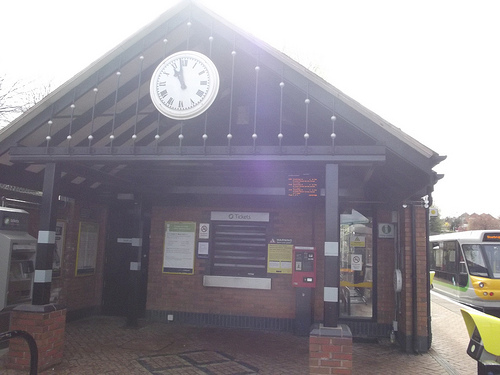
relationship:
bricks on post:
[302, 322, 359, 372] [319, 153, 354, 337]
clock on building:
[139, 47, 227, 119] [1, 0, 443, 359]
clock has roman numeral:
[149, 50, 221, 121] [194, 61, 200, 71]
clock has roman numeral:
[149, 50, 221, 121] [198, 76, 210, 88]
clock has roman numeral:
[149, 50, 221, 121] [176, 97, 185, 114]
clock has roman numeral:
[149, 50, 221, 121] [154, 86, 168, 100]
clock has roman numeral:
[149, 50, 221, 121] [159, 64, 169, 76]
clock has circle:
[149, 50, 221, 121] [175, 78, 189, 96]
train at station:
[427, 228, 499, 315] [6, 7, 498, 372]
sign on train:
[482, 230, 499, 244] [430, 230, 499, 307]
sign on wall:
[156, 217, 197, 277] [145, 200, 318, 337]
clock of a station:
[149, 50, 221, 121] [6, 7, 498, 372]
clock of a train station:
[149, 50, 221, 121] [4, 0, 455, 374]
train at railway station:
[424, 220, 499, 317] [0, 0, 472, 375]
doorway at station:
[89, 207, 143, 324] [6, 7, 498, 372]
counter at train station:
[139, 203, 336, 333] [4, 0, 455, 374]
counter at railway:
[143, 201, 337, 329] [5, 5, 498, 364]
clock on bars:
[149, 50, 221, 121] [45, 19, 345, 156]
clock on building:
[149, 50, 221, 121] [58, 59, 403, 174]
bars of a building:
[45, 19, 345, 156] [58, 59, 403, 174]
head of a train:
[458, 231, 498, 292] [425, 226, 498, 314]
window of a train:
[13, 191, 55, 251] [403, 194, 493, 336]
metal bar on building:
[106, 66, 123, 155] [1, 0, 443, 359]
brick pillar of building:
[391, 197, 434, 357] [1, 0, 443, 359]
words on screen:
[287, 171, 316, 198] [283, 164, 322, 205]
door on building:
[98, 199, 147, 324] [11, 26, 456, 358]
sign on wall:
[72, 215, 99, 280] [58, 185, 108, 319]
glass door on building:
[332, 200, 377, 325] [1, 0, 443, 359]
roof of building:
[1, 1, 446, 186] [1, 0, 443, 359]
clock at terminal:
[149, 50, 221, 121] [1, 0, 446, 356]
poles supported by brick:
[30, 154, 63, 316] [14, 309, 66, 362]